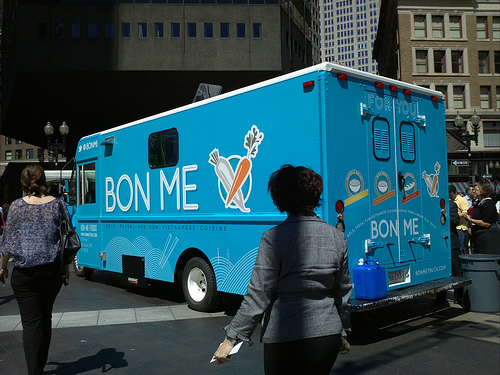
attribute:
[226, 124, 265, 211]
carrot — orange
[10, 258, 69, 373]
pants — black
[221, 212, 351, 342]
shirt — grey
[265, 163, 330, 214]
hair — black, short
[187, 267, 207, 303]
rim — white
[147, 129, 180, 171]
window — black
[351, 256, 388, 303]
container — blue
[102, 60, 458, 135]
roof — white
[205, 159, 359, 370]
woman — holding, dressed, walking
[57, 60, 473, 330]
truck — blue, parked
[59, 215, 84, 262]
purse — black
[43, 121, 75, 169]
lamp — standing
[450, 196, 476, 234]
shirt — yellow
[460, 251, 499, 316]
bin — black, grey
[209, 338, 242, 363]
envelop — white